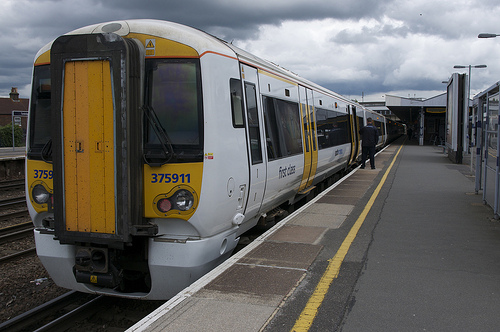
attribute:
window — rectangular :
[258, 93, 327, 162]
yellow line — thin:
[290, 193, 375, 330]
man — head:
[357, 116, 382, 170]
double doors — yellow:
[300, 88, 317, 193]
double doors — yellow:
[346, 102, 357, 164]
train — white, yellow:
[25, 16, 402, 303]